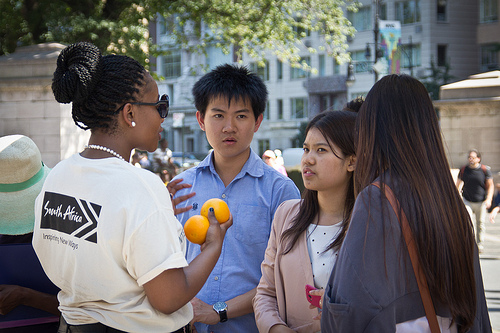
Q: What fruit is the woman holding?
A: Oranges.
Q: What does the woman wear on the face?
A: Sunglasses.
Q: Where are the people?
A: On the street.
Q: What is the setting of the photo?
A: Urban.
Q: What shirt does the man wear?
A: A blue shirt.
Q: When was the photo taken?
A: During the daytime.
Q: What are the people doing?
A: Talking.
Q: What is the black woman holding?
A: Oranges.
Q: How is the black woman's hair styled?
A: In braids.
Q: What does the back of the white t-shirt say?
A: South Africa.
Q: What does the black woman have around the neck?
A: Necklace.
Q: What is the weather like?
A: Sunny.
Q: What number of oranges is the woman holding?
A: Two.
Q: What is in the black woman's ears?
A: Earrings.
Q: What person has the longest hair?
A: The woman in a grey sweater.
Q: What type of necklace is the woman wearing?
A: Pearl.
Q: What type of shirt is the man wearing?
A: Button down.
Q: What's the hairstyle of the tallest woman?
A: Braids in a bun.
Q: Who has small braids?
A: Tallest woman.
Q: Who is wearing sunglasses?
A: Tallest woman.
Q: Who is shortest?
A: Woman wearing polka dots.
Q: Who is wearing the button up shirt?
A: The man.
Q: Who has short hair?
A: The man.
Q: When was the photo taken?
A: Daytime.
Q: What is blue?
A: Man's shirt.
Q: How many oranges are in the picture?
A: Two.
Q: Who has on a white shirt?
A: Woman on left.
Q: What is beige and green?
A: A hat.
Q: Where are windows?
A: On a building.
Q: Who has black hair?
A: Man in blue.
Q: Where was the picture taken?
A: On the sidewalk.